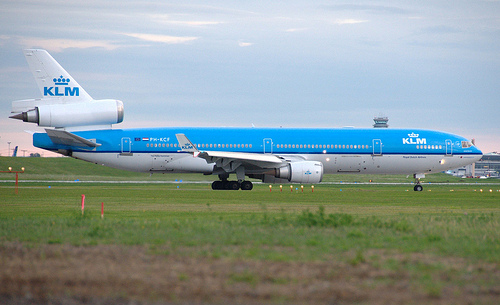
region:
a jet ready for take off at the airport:
[5, 45, 483, 205]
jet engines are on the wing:
[257, 156, 323, 186]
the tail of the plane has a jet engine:
[5, 46, 121, 182]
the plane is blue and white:
[7, 47, 482, 203]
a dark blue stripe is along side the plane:
[35, 130, 485, 176]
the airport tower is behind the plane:
[367, 115, 392, 185]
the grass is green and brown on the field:
[3, 156, 494, 299]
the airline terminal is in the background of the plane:
[440, 130, 498, 182]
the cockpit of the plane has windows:
[458, 131, 483, 172]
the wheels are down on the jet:
[205, 152, 428, 197]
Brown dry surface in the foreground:
[7, 248, 438, 303]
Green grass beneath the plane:
[15, 198, 487, 240]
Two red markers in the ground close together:
[77, 192, 106, 220]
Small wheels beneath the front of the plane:
[409, 181, 427, 198]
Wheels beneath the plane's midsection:
[204, 178, 254, 191]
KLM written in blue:
[41, 83, 81, 98]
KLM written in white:
[400, 135, 429, 146]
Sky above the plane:
[111, 14, 441, 81]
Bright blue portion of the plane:
[31, 124, 481, 153]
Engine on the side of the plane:
[273, 158, 324, 185]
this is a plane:
[3, 42, 485, 195]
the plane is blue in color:
[13, 43, 489, 195]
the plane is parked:
[0, 45, 494, 182]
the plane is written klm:
[44, 80, 84, 99]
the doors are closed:
[252, 137, 390, 149]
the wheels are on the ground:
[207, 174, 262, 191]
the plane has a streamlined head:
[434, 135, 483, 170]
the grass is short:
[163, 198, 421, 290]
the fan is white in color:
[23, 92, 118, 125]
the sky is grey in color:
[152, 6, 463, 99]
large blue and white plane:
[6, 29, 485, 222]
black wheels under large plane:
[198, 167, 427, 193]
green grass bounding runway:
[5, 137, 498, 249]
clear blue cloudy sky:
[3, 0, 496, 163]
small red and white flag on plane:
[138, 133, 160, 145]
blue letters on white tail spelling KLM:
[39, 71, 81, 107]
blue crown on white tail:
[51, 70, 72, 85]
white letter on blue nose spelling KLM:
[396, 133, 429, 150]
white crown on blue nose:
[408, 130, 425, 137]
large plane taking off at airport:
[8, 43, 488, 215]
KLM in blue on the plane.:
[36, 67, 104, 108]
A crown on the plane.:
[50, 78, 87, 95]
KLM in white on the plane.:
[397, 127, 434, 159]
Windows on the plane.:
[323, 141, 341, 157]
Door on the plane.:
[369, 142, 389, 164]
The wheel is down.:
[411, 182, 442, 198]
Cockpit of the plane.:
[458, 137, 481, 157]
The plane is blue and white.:
[328, 135, 342, 177]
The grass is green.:
[204, 198, 255, 224]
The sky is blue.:
[267, 52, 346, 71]